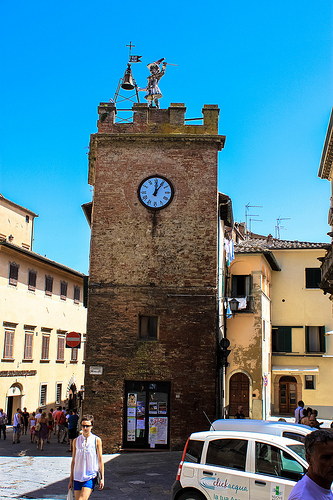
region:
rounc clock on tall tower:
[132, 170, 177, 210]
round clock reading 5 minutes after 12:
[133, 171, 175, 210]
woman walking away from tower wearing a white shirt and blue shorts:
[64, 410, 107, 498]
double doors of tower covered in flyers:
[123, 378, 172, 452]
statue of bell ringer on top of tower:
[133, 56, 180, 106]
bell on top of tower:
[104, 59, 144, 122]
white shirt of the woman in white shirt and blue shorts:
[70, 431, 99, 481]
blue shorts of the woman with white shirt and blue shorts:
[68, 471, 97, 490]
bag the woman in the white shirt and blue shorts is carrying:
[64, 484, 71, 496]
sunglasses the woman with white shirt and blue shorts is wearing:
[81, 424, 92, 426]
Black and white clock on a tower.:
[135, 173, 175, 212]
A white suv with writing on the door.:
[168, 429, 313, 499]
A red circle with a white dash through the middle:
[65, 331, 81, 349]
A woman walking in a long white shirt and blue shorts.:
[68, 413, 106, 498]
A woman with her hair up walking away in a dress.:
[34, 411, 48, 450]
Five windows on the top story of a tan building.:
[6, 262, 81, 305]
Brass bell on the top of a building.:
[121, 71, 134, 90]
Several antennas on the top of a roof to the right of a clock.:
[243, 199, 290, 241]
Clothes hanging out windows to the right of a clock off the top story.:
[217, 231, 234, 268]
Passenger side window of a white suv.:
[253, 439, 308, 483]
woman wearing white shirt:
[67, 415, 104, 496]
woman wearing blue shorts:
[67, 414, 104, 495]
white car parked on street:
[169, 431, 325, 494]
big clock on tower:
[137, 175, 174, 209]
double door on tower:
[121, 380, 169, 448]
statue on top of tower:
[143, 60, 167, 105]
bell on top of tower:
[113, 64, 140, 106]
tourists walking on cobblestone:
[0, 401, 76, 450]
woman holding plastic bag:
[65, 416, 105, 498]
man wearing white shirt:
[288, 429, 331, 499]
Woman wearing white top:
[68, 411, 107, 499]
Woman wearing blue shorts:
[69, 411, 105, 498]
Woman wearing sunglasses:
[64, 409, 104, 499]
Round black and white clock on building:
[137, 171, 172, 208]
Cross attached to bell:
[124, 37, 135, 60]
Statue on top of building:
[138, 53, 181, 103]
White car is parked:
[167, 423, 305, 497]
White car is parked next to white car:
[211, 415, 331, 474]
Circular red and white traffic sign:
[63, 330, 82, 351]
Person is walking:
[11, 403, 24, 442]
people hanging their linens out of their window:
[224, 294, 247, 320]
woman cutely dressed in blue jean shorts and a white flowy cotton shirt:
[65, 413, 105, 499]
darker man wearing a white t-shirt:
[285, 428, 331, 499]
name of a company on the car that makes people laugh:
[211, 475, 248, 494]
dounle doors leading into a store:
[116, 378, 173, 445]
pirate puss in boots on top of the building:
[106, 36, 174, 118]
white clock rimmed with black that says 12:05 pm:
[135, 172, 172, 209]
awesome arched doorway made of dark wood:
[226, 368, 253, 418]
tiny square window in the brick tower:
[135, 312, 159, 342]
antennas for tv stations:
[242, 200, 297, 239]